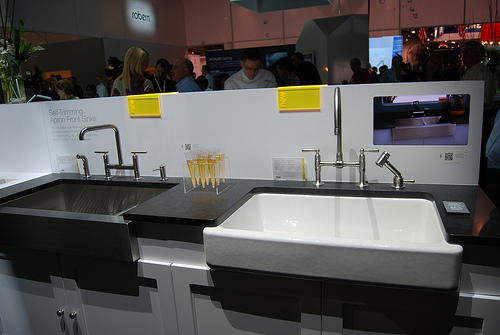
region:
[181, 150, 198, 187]
shot in the tray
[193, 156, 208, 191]
shot in the tray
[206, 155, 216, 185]
shot in the tray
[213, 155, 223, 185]
shot in the tray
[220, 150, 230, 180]
shot in the tray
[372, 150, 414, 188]
sprayer on the sink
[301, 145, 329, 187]
knob on the sink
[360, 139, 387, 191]
knob on the sink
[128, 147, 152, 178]
knob on the sink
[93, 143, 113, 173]
knob on the sink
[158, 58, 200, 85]
the head of a man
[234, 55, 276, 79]
the ear of a man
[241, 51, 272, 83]
the eye of a man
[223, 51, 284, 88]
a man wearing a shirt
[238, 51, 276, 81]
the face of a man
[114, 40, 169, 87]
the head of a woman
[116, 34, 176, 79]
the hair of a woman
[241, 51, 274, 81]
the forehead of a man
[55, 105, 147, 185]
a fossett on a sink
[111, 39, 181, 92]
a woman wearing a shirt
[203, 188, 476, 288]
white farm sink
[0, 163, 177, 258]
black farm sink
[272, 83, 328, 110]
yellow markers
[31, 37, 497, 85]
people walking around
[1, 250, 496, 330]
white cabinets with chrome hardware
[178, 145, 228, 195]
container with test tubes in it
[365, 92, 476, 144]
picture hanging on the wall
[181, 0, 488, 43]
cabinets behind the people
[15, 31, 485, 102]
people walking around a showroom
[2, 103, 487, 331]
a kitchen showroom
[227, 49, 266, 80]
A person tanding on a room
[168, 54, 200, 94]
A person tanding on a room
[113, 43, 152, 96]
A person tanding on a room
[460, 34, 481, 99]
A person tanding on a room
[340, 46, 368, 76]
A person tanding on a room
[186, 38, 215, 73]
A person tanding on a room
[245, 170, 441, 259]
A clean water tap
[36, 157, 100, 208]
A clean water tap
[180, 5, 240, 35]
a pink house wall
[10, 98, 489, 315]
two sinks in counter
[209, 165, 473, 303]
white sink in counter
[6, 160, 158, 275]
silver sink in counter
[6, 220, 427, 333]
white lower cabinets under sink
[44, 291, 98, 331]
silver nobs on cabinet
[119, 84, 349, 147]
yellow post on wall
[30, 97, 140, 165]
white sign on wall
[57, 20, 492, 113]
people standing behind wall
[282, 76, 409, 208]
silver faucet fixture on sink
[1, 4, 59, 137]
green plant on side